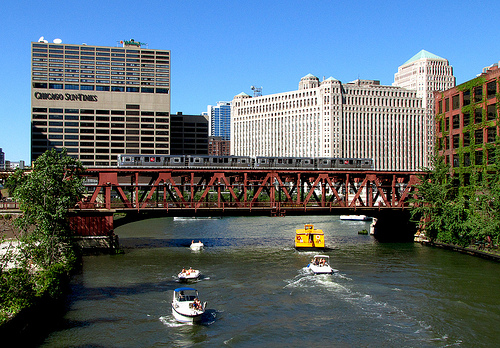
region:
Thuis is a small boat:
[169, 285, 224, 325]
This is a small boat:
[179, 260, 205, 283]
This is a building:
[26, 31, 172, 188]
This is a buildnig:
[228, 75, 425, 162]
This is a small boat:
[306, 251, 343, 278]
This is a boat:
[290, 223, 329, 255]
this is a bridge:
[7, 167, 432, 211]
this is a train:
[117, 152, 378, 174]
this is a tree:
[11, 156, 76, 269]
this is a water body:
[46, 220, 487, 347]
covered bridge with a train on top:
[111, 155, 410, 210]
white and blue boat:
[172, 286, 200, 323]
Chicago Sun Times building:
[35, 55, 162, 146]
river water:
[223, 283, 486, 342]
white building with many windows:
[257, 101, 427, 152]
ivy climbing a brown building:
[450, 92, 499, 188]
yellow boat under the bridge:
[295, 226, 324, 248]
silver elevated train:
[119, 154, 371, 167]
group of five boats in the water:
[178, 230, 326, 315]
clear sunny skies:
[177, 37, 370, 69]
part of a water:
[240, 250, 300, 300]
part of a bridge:
[233, 172, 278, 213]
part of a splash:
[312, 259, 349, 312]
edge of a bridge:
[218, 187, 264, 228]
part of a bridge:
[221, 143, 268, 205]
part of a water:
[236, 274, 274, 320]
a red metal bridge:
[9, 165, 429, 222]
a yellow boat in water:
[278, 220, 331, 251]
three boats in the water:
[161, 225, 224, 343]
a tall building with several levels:
[38, 35, 177, 172]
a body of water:
[28, 157, 463, 345]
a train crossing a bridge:
[79, 145, 395, 194]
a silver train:
[101, 150, 379, 177]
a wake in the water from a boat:
[283, 242, 362, 314]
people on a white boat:
[165, 264, 213, 279]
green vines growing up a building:
[428, 69, 494, 216]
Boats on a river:
[127, 220, 379, 335]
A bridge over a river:
[61, 145, 436, 252]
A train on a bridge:
[108, 143, 382, 213]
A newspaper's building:
[20, 28, 180, 160]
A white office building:
[225, 31, 461, 153]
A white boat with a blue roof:
[161, 280, 217, 338]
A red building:
[426, 55, 498, 237]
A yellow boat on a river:
[286, 217, 335, 254]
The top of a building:
[387, 37, 462, 84]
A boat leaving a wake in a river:
[293, 249, 419, 340]